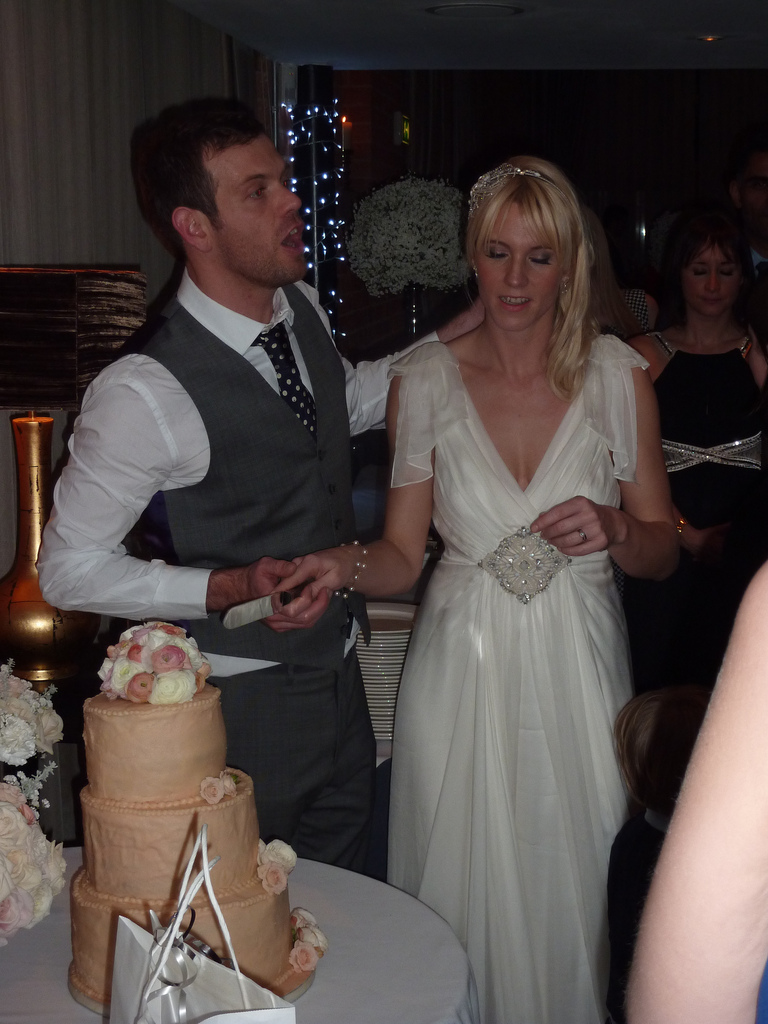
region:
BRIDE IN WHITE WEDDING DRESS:
[399, 152, 684, 697]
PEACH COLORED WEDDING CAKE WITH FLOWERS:
[63, 616, 332, 1018]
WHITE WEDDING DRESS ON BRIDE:
[375, 340, 666, 1022]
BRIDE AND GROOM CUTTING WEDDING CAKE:
[26, 83, 712, 1003]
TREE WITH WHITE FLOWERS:
[335, 173, 473, 293]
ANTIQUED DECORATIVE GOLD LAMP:
[5, 218, 154, 692]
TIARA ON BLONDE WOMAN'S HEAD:
[455, 162, 584, 222]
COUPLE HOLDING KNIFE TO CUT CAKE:
[218, 576, 358, 639]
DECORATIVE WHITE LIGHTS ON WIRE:
[279, 61, 354, 346]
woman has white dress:
[318, 134, 695, 1022]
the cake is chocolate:
[54, 604, 344, 1023]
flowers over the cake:
[190, 762, 248, 808]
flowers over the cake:
[246, 826, 307, 901]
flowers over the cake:
[278, 896, 340, 991]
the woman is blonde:
[366, 139, 673, 544]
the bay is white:
[100, 810, 307, 1022]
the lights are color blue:
[291, 84, 380, 334]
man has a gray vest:
[22, 97, 400, 881]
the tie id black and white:
[256, 314, 331, 451]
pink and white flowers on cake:
[93, 621, 213, 701]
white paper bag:
[109, 916, 270, 1019]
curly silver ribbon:
[156, 927, 205, 1018]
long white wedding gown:
[388, 346, 604, 1010]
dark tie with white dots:
[255, 327, 328, 430]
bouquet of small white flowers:
[340, 175, 471, 300]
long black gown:
[651, 347, 761, 665]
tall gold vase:
[5, 411, 98, 685]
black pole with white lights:
[285, 63, 347, 346]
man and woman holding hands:
[44, 93, 672, 1022]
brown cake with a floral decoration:
[66, 603, 323, 1019]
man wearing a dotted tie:
[37, 98, 388, 881]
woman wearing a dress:
[274, 152, 686, 1022]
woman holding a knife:
[218, 156, 680, 1022]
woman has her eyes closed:
[600, 214, 766, 676]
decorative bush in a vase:
[335, 173, 475, 347]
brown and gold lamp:
[1, 264, 153, 680]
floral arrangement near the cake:
[0, 615, 320, 1018]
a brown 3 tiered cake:
[68, 598, 328, 1020]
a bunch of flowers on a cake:
[88, 609, 231, 742]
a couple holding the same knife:
[222, 544, 349, 658]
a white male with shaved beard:
[108, 82, 350, 327]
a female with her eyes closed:
[465, 152, 596, 331]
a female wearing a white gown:
[388, 150, 674, 765]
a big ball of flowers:
[341, 171, 488, 304]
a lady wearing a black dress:
[627, 209, 767, 405]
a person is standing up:
[269, 160, 653, 1022]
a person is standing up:
[44, 103, 480, 863]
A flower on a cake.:
[288, 941, 325, 976]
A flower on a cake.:
[292, 929, 328, 949]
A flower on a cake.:
[291, 906, 315, 934]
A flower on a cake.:
[257, 864, 287, 898]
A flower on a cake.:
[262, 841, 298, 877]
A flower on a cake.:
[222, 770, 242, 795]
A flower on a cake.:
[199, 777, 225, 803]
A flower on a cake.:
[122, 668, 154, 700]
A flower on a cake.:
[154, 642, 194, 670]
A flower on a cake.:
[255, 864, 286, 888]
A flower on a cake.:
[261, 842, 297, 869]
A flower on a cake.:
[290, 944, 318, 967]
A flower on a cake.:
[298, 921, 325, 950]